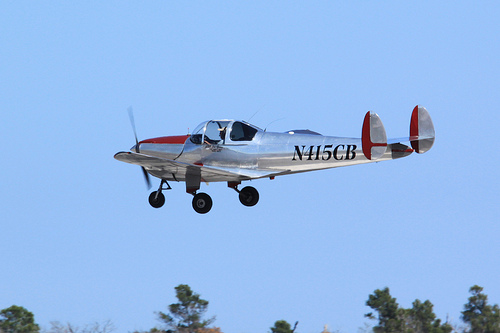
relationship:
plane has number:
[94, 89, 464, 250] [276, 129, 348, 165]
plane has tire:
[94, 89, 464, 250] [217, 181, 265, 206]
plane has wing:
[94, 89, 464, 250] [105, 145, 212, 173]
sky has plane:
[187, 17, 259, 51] [94, 89, 464, 250]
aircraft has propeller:
[94, 89, 464, 250] [97, 134, 158, 197]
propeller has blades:
[97, 134, 158, 197] [97, 90, 159, 183]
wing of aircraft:
[105, 145, 212, 173] [94, 89, 464, 250]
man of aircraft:
[200, 123, 226, 146] [94, 89, 464, 250]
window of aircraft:
[195, 114, 257, 148] [94, 89, 464, 250]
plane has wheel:
[94, 89, 464, 250] [221, 184, 297, 213]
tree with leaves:
[391, 290, 449, 330] [385, 289, 428, 331]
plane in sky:
[94, 89, 464, 250] [187, 17, 259, 51]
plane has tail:
[94, 89, 464, 250] [340, 90, 443, 160]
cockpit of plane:
[182, 98, 278, 153] [94, 89, 464, 250]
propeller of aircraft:
[97, 134, 158, 197] [94, 89, 464, 250]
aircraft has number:
[94, 89, 464, 250] [276, 129, 348, 165]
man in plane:
[200, 106, 238, 158] [94, 89, 464, 250]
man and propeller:
[200, 123, 226, 146] [97, 134, 158, 197]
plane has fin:
[94, 89, 464, 250] [372, 81, 447, 151]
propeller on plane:
[97, 134, 158, 197] [94, 89, 464, 250]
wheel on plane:
[221, 184, 297, 213] [94, 89, 464, 250]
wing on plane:
[105, 145, 212, 173] [94, 89, 464, 250]